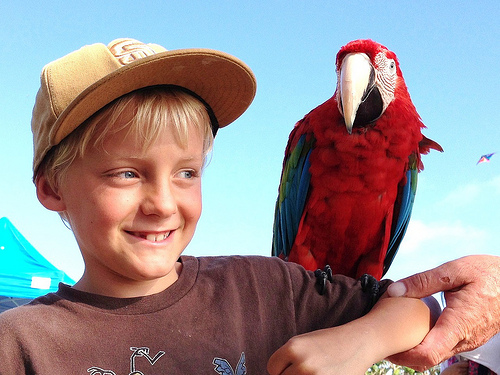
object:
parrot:
[271, 37, 445, 305]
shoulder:
[220, 254, 318, 312]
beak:
[338, 51, 375, 135]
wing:
[270, 117, 321, 258]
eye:
[389, 61, 395, 70]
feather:
[418, 133, 444, 154]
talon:
[320, 276, 327, 295]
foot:
[312, 263, 335, 296]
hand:
[381, 253, 499, 372]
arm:
[267, 256, 443, 374]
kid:
[0, 37, 444, 375]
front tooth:
[156, 234, 165, 242]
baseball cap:
[29, 37, 256, 176]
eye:
[173, 168, 198, 179]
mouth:
[121, 224, 182, 247]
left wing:
[380, 146, 423, 278]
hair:
[32, 84, 214, 231]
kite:
[476, 152, 496, 166]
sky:
[1, 0, 499, 282]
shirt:
[0, 253, 396, 375]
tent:
[0, 216, 80, 312]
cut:
[457, 258, 497, 283]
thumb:
[386, 256, 474, 300]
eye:
[104, 168, 141, 180]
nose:
[140, 175, 179, 218]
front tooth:
[145, 234, 155, 241]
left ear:
[35, 173, 66, 211]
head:
[334, 38, 409, 136]